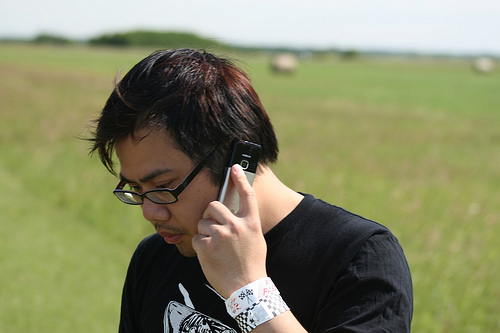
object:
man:
[86, 49, 413, 331]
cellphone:
[213, 140, 265, 214]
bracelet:
[224, 279, 290, 320]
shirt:
[113, 190, 414, 332]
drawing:
[162, 283, 240, 332]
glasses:
[113, 138, 224, 206]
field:
[1, 41, 500, 333]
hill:
[95, 29, 226, 44]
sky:
[1, 0, 500, 55]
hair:
[92, 49, 280, 184]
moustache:
[151, 223, 188, 237]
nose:
[142, 188, 169, 225]